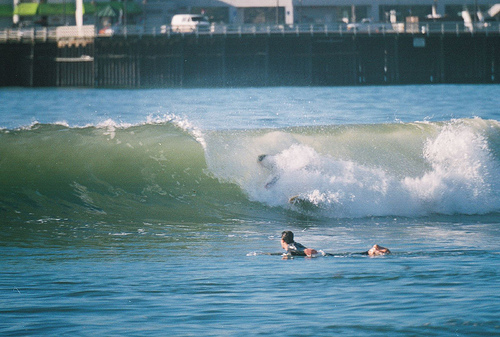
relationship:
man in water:
[281, 230, 319, 260] [5, 88, 497, 334]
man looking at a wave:
[281, 230, 319, 260] [0, 116, 497, 239]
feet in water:
[367, 236, 398, 264] [5, 88, 497, 334]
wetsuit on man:
[285, 244, 329, 256] [278, 232, 391, 257]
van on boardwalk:
[168, 4, 226, 39] [0, 21, 500, 90]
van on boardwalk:
[171, 13, 211, 34] [0, 21, 499, 83]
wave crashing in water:
[262, 109, 473, 220] [5, 88, 497, 334]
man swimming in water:
[281, 230, 319, 260] [5, 88, 497, 334]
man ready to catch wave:
[281, 230, 319, 260] [39, 112, 420, 204]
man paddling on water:
[281, 230, 319, 260] [5, 134, 474, 316]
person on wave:
[252, 148, 340, 221] [0, 113, 499, 222]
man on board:
[279, 230, 389, 265] [246, 244, 391, 259]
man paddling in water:
[281, 230, 319, 260] [5, 88, 497, 334]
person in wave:
[255, 153, 332, 216] [140, 130, 336, 215]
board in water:
[290, 190, 332, 220] [5, 88, 497, 334]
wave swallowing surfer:
[10, 100, 498, 220] [250, 141, 319, 216]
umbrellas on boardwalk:
[6, 0, 143, 27] [0, 21, 500, 90]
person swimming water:
[255, 153, 332, 216] [5, 88, 497, 334]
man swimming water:
[281, 230, 319, 260] [5, 88, 497, 334]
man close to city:
[281, 230, 319, 260] [4, 4, 492, 73]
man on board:
[281, 230, 319, 260] [253, 254, 425, 258]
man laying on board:
[281, 230, 319, 260] [241, 248, 378, 260]